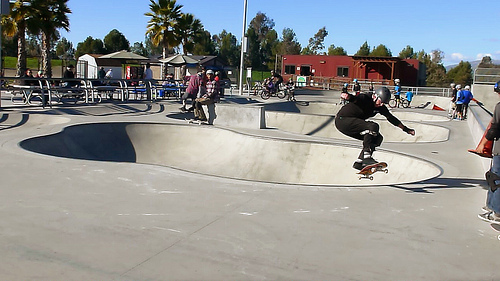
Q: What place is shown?
A: It is a skate park.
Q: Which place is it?
A: It is a skate park.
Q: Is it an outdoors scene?
A: Yes, it is outdoors.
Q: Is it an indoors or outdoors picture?
A: It is outdoors.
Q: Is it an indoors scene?
A: No, it is outdoors.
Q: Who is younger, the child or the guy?
A: The child is younger than the guy.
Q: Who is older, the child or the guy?
A: The guy is older than the child.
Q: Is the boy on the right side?
A: Yes, the boy is on the right of the image.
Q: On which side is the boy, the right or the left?
A: The boy is on the right of the image.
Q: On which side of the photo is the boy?
A: The boy is on the right of the image.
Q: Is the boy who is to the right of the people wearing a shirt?
A: Yes, the boy is wearing a shirt.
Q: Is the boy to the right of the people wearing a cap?
A: No, the boy is wearing a shirt.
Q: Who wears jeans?
A: The boy wears jeans.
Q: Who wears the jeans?
A: The boy wears jeans.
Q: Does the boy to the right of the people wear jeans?
A: Yes, the boy wears jeans.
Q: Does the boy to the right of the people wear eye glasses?
A: No, the boy wears jeans.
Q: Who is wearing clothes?
A: The boy is wearing clothes.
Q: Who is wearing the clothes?
A: The boy is wearing clothes.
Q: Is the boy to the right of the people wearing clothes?
A: Yes, the boy is wearing clothes.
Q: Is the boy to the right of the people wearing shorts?
A: No, the boy is wearing clothes.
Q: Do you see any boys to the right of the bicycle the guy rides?
A: Yes, there is a boy to the right of the bicycle.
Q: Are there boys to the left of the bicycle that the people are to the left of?
A: No, the boy is to the right of the bicycle.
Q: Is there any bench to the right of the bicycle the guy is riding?
A: No, there is a boy to the right of the bicycle.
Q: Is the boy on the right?
A: Yes, the boy is on the right of the image.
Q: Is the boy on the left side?
A: No, the boy is on the right of the image.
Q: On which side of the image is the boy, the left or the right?
A: The boy is on the right of the image.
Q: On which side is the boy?
A: The boy is on the right of the image.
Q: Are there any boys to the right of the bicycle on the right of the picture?
A: Yes, there is a boy to the right of the bicycle.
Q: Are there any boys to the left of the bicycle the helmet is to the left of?
A: No, the boy is to the right of the bicycle.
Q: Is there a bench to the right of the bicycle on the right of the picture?
A: No, there is a boy to the right of the bicycle.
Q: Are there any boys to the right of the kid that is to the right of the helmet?
A: Yes, there is a boy to the right of the child.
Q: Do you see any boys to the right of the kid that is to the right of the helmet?
A: Yes, there is a boy to the right of the child.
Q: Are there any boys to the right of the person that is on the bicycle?
A: Yes, there is a boy to the right of the child.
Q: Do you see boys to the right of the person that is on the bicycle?
A: Yes, there is a boy to the right of the child.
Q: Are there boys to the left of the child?
A: No, the boy is to the right of the child.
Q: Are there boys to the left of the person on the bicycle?
A: No, the boy is to the right of the child.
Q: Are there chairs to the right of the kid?
A: No, there is a boy to the right of the kid.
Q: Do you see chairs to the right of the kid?
A: No, there is a boy to the right of the kid.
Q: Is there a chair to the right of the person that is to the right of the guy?
A: No, there is a boy to the right of the kid.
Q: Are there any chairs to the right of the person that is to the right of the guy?
A: No, there is a boy to the right of the kid.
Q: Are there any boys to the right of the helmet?
A: Yes, there is a boy to the right of the helmet.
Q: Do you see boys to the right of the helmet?
A: Yes, there is a boy to the right of the helmet.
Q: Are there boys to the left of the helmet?
A: No, the boy is to the right of the helmet.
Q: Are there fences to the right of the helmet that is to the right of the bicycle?
A: No, there is a boy to the right of the helmet.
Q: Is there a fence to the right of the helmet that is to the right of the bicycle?
A: No, there is a boy to the right of the helmet.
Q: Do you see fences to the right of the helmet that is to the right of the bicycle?
A: No, there is a boy to the right of the helmet.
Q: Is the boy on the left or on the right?
A: The boy is on the right of the image.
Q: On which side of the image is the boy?
A: The boy is on the right of the image.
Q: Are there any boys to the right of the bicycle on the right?
A: Yes, there is a boy to the right of the bicycle.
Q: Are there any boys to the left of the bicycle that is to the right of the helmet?
A: No, the boy is to the right of the bicycle.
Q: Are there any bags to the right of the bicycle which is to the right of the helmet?
A: No, there is a boy to the right of the bicycle.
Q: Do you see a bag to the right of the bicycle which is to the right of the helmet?
A: No, there is a boy to the right of the bicycle.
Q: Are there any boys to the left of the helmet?
A: No, the boy is to the right of the helmet.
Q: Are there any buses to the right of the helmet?
A: No, there is a boy to the right of the helmet.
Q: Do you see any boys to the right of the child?
A: Yes, there is a boy to the right of the child.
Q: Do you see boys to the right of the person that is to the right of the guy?
A: Yes, there is a boy to the right of the child.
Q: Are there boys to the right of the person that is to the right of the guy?
A: Yes, there is a boy to the right of the child.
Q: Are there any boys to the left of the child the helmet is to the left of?
A: No, the boy is to the right of the child.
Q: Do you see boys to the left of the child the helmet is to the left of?
A: No, the boy is to the right of the child.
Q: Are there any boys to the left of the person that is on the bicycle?
A: No, the boy is to the right of the child.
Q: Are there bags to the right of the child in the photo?
A: No, there is a boy to the right of the child.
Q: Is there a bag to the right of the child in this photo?
A: No, there is a boy to the right of the child.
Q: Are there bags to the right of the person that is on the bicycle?
A: No, there is a boy to the right of the child.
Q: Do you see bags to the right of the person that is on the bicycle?
A: No, there is a boy to the right of the child.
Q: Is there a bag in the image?
A: No, there are no bags.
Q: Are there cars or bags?
A: No, there are no bags or cars.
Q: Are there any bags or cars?
A: No, there are no bags or cars.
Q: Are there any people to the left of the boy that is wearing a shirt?
A: Yes, there are people to the left of the boy.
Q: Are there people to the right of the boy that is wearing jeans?
A: No, the people are to the left of the boy.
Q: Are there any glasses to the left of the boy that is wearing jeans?
A: No, there are people to the left of the boy.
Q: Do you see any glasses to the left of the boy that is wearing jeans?
A: No, there are people to the left of the boy.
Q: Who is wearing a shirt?
A: The people are wearing a shirt.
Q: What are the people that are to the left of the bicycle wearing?
A: The people are wearing a shirt.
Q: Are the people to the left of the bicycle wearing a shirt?
A: Yes, the people are wearing a shirt.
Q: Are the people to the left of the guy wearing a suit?
A: No, the people are wearing a shirt.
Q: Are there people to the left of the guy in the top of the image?
A: Yes, there are people to the left of the guy.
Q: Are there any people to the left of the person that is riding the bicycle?
A: Yes, there are people to the left of the guy.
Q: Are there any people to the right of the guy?
A: No, the people are to the left of the guy.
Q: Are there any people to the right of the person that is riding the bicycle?
A: No, the people are to the left of the guy.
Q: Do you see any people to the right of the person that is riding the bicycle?
A: No, the people are to the left of the guy.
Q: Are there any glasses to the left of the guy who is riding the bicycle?
A: No, there are people to the left of the guy.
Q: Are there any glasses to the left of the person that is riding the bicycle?
A: No, there are people to the left of the guy.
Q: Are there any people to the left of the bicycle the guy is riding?
A: Yes, there are people to the left of the bicycle.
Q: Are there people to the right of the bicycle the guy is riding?
A: No, the people are to the left of the bicycle.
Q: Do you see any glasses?
A: No, there are no glasses.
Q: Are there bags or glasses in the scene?
A: No, there are no glasses or bags.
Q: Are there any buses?
A: No, there are no buses.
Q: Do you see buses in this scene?
A: No, there are no buses.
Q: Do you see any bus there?
A: No, there are no buses.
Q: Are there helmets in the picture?
A: Yes, there is a helmet.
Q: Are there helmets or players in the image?
A: Yes, there is a helmet.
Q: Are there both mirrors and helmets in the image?
A: No, there is a helmet but no mirrors.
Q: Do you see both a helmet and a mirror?
A: No, there is a helmet but no mirrors.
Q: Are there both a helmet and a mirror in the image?
A: No, there is a helmet but no mirrors.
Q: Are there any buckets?
A: No, there are no buckets.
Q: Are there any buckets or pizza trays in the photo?
A: No, there are no buckets or pizza trays.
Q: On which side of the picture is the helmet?
A: The helmet is on the right of the image.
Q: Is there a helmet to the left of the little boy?
A: Yes, there is a helmet to the left of the boy.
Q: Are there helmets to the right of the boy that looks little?
A: No, the helmet is to the left of the boy.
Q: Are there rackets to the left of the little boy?
A: No, there is a helmet to the left of the boy.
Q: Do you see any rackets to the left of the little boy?
A: No, there is a helmet to the left of the boy.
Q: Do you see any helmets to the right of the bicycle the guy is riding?
A: Yes, there is a helmet to the right of the bicycle.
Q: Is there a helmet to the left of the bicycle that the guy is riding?
A: No, the helmet is to the right of the bicycle.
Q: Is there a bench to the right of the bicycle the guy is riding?
A: No, there is a helmet to the right of the bicycle.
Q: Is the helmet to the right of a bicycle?
A: Yes, the helmet is to the right of a bicycle.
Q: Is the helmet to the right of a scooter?
A: No, the helmet is to the right of a bicycle.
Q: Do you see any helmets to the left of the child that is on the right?
A: Yes, there is a helmet to the left of the kid.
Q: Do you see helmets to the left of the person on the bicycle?
A: Yes, there is a helmet to the left of the kid.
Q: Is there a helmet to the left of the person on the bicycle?
A: Yes, there is a helmet to the left of the kid.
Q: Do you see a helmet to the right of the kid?
A: No, the helmet is to the left of the kid.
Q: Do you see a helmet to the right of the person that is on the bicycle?
A: No, the helmet is to the left of the kid.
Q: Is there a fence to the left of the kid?
A: No, there is a helmet to the left of the kid.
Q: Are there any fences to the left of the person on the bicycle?
A: No, there is a helmet to the left of the kid.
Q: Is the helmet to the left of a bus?
A: No, the helmet is to the left of a child.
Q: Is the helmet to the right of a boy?
A: No, the helmet is to the left of a boy.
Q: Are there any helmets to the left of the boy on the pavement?
A: Yes, there is a helmet to the left of the boy.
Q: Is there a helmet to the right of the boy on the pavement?
A: No, the helmet is to the left of the boy.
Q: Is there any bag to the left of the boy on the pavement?
A: No, there is a helmet to the left of the boy.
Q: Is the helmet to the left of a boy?
A: Yes, the helmet is to the left of a boy.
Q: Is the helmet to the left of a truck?
A: No, the helmet is to the left of a boy.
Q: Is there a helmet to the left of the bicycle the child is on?
A: Yes, there is a helmet to the left of the bicycle.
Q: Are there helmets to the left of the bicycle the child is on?
A: Yes, there is a helmet to the left of the bicycle.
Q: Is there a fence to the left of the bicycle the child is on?
A: No, there is a helmet to the left of the bicycle.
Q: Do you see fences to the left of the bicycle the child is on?
A: No, there is a helmet to the left of the bicycle.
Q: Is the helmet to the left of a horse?
A: No, the helmet is to the left of a bicycle.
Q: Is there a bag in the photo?
A: No, there are no bags.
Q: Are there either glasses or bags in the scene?
A: No, there are no bags or glasses.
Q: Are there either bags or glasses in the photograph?
A: No, there are no bags or glasses.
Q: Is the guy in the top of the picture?
A: Yes, the guy is in the top of the image.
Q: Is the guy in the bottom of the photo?
A: No, the guy is in the top of the image.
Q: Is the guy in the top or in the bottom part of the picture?
A: The guy is in the top of the image.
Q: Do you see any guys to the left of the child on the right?
A: Yes, there is a guy to the left of the kid.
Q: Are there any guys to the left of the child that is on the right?
A: Yes, there is a guy to the left of the kid.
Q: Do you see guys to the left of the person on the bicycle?
A: Yes, there is a guy to the left of the kid.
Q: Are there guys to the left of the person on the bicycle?
A: Yes, there is a guy to the left of the kid.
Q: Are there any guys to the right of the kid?
A: No, the guy is to the left of the kid.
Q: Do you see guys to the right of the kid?
A: No, the guy is to the left of the kid.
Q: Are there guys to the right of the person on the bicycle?
A: No, the guy is to the left of the kid.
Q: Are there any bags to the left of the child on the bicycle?
A: No, there is a guy to the left of the kid.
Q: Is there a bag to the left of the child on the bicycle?
A: No, there is a guy to the left of the kid.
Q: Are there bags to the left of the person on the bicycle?
A: No, there is a guy to the left of the kid.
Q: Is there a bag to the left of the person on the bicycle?
A: No, there is a guy to the left of the kid.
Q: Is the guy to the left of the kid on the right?
A: Yes, the guy is to the left of the child.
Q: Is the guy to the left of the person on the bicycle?
A: Yes, the guy is to the left of the child.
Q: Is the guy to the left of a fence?
A: No, the guy is to the left of the child.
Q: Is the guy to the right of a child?
A: No, the guy is to the left of a child.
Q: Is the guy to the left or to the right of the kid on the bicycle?
A: The guy is to the left of the kid.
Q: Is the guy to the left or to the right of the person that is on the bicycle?
A: The guy is to the left of the kid.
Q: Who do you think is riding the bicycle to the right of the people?
A: The guy is riding the bicycle.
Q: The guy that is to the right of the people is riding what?
A: The guy is riding the bicycle.